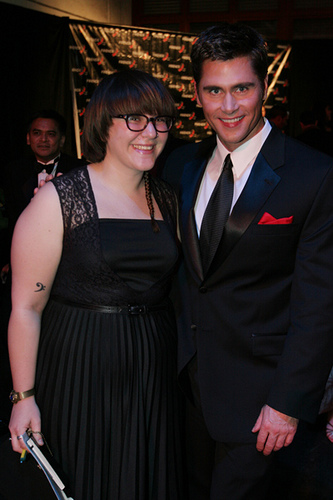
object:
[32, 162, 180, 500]
dress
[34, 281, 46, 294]
tattoo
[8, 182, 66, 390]
arm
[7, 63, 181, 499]
woman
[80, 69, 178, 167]
short hair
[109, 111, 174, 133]
glasses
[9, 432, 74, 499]
notebook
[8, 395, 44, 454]
hand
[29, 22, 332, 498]
man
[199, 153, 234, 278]
tie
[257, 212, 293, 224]
handkerchief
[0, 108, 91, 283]
man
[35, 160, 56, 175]
bowtie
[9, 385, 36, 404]
bracelet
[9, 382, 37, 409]
wrist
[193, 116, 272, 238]
white shirt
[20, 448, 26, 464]
pen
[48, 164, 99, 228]
shoulder strap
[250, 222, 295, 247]
pocket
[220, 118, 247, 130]
lips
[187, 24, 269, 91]
hair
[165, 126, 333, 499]
black suit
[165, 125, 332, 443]
coat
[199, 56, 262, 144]
face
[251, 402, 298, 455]
left hand